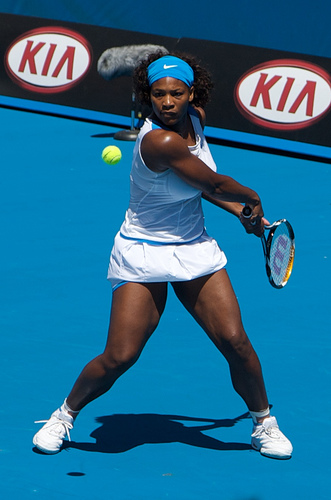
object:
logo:
[163, 64, 177, 70]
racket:
[242, 205, 296, 288]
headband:
[147, 55, 194, 88]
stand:
[97, 44, 175, 140]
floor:
[4, 107, 324, 493]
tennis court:
[1, 2, 331, 499]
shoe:
[32, 408, 73, 454]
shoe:
[251, 416, 294, 460]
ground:
[255, 87, 272, 101]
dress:
[106, 105, 228, 292]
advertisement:
[234, 60, 331, 132]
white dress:
[106, 110, 227, 284]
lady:
[33, 52, 295, 461]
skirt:
[107, 228, 228, 292]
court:
[6, 26, 321, 461]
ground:
[1, 87, 328, 498]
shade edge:
[85, 447, 128, 455]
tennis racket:
[241, 205, 295, 289]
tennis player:
[31, 48, 293, 458]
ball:
[101, 145, 121, 164]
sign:
[4, 26, 331, 132]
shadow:
[60, 404, 275, 454]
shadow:
[66, 471, 86, 477]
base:
[102, 145, 122, 165]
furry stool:
[97, 44, 170, 140]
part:
[13, 171, 111, 278]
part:
[51, 191, 82, 218]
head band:
[146, 55, 194, 88]